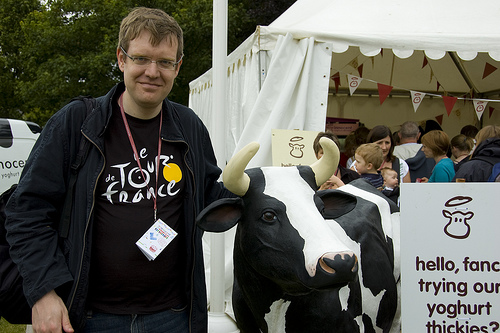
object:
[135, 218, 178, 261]
id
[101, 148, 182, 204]
logo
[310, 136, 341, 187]
horn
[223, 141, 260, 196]
horn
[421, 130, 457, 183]
woman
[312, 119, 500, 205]
people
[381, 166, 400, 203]
child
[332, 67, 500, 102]
string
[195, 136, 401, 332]
cow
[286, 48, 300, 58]
ground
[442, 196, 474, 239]
head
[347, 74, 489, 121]
banner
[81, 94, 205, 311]
shirt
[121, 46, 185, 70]
glasses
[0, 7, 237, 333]
man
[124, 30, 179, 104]
face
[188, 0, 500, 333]
tent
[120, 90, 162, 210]
lanyard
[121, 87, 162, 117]
neck